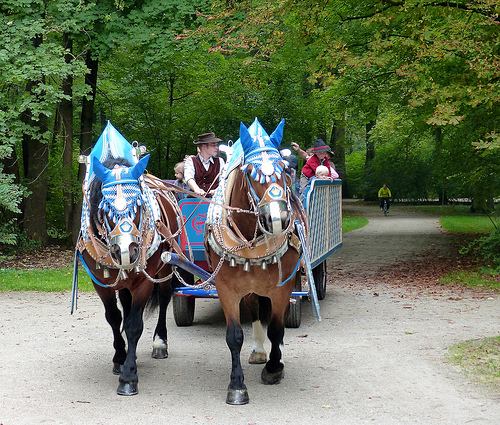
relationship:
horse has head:
[70, 150, 189, 398] [86, 153, 158, 274]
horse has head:
[202, 117, 312, 409] [231, 121, 302, 234]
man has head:
[179, 127, 229, 196] [190, 129, 229, 147]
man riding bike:
[377, 183, 395, 201] [377, 193, 392, 221]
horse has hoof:
[70, 150, 189, 398] [116, 367, 141, 400]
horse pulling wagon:
[70, 150, 189, 398] [173, 174, 347, 333]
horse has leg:
[202, 117, 312, 409] [245, 292, 272, 369]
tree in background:
[300, 7, 402, 197] [8, 4, 499, 280]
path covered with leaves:
[5, 195, 494, 424] [324, 230, 488, 306]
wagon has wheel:
[173, 174, 347, 333] [170, 270, 198, 326]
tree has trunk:
[300, 7, 402, 197] [324, 114, 358, 202]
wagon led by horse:
[173, 174, 347, 333] [70, 150, 189, 398]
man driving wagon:
[179, 127, 229, 196] [173, 174, 347, 333]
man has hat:
[179, 127, 229, 196] [191, 126, 226, 144]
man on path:
[377, 183, 395, 201] [5, 195, 494, 424]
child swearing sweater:
[293, 143, 340, 205] [303, 156, 332, 178]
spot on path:
[294, 330, 313, 348] [5, 195, 494, 424]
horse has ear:
[70, 150, 189, 398] [132, 149, 152, 182]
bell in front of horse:
[117, 265, 134, 287] [70, 150, 189, 398]